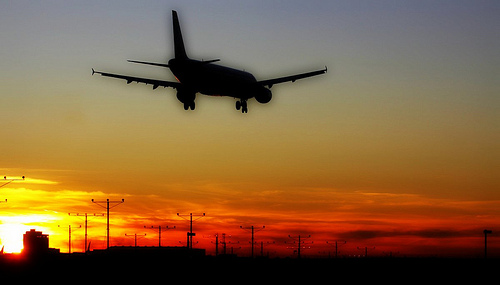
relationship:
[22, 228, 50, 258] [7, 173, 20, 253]
building in front of sunset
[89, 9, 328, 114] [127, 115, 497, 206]
plane in sky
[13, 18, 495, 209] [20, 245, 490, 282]
sky over land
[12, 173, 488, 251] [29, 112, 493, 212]
clouds in sky